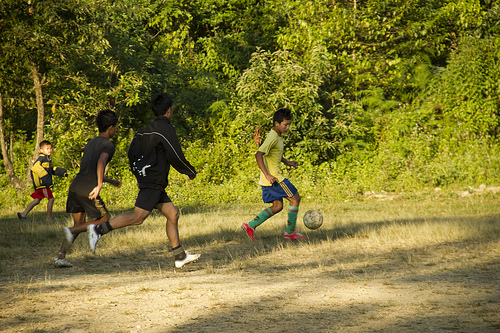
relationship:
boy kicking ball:
[241, 108, 302, 243] [302, 210, 323, 231]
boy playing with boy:
[241, 108, 302, 243] [86, 91, 202, 267]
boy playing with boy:
[241, 108, 302, 243] [47, 109, 120, 277]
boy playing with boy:
[241, 108, 302, 243] [3, 137, 73, 225]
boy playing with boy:
[86, 91, 202, 267] [241, 108, 302, 243]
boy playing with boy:
[86, 91, 202, 267] [47, 109, 120, 277]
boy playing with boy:
[86, 91, 202, 267] [3, 137, 73, 225]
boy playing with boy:
[47, 109, 120, 277] [241, 108, 302, 243]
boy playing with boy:
[47, 109, 120, 277] [86, 91, 202, 267]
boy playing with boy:
[47, 109, 120, 277] [3, 137, 73, 225]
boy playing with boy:
[3, 137, 73, 225] [241, 108, 302, 243]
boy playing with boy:
[3, 137, 73, 225] [86, 91, 202, 267]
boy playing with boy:
[3, 137, 73, 225] [47, 109, 120, 277]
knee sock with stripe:
[286, 206, 301, 235] [287, 208, 299, 218]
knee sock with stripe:
[249, 207, 274, 231] [262, 204, 273, 220]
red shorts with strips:
[30, 187, 53, 200] [41, 189, 48, 198]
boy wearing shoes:
[86, 91, 202, 267] [173, 252, 204, 268]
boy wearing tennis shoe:
[86, 91, 202, 267] [84, 221, 101, 251]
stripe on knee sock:
[284, 210, 300, 215] [287, 205, 302, 234]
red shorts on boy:
[25, 186, 55, 199] [16, 139, 67, 221]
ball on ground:
[297, 192, 332, 242] [243, 205, 498, 305]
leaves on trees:
[299, 55, 347, 92] [189, 9, 412, 114]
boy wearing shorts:
[240, 105, 308, 243] [260, 176, 300, 203]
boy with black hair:
[240, 105, 308, 243] [273, 106, 294, 123]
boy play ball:
[241, 108, 302, 243] [302, 210, 323, 231]